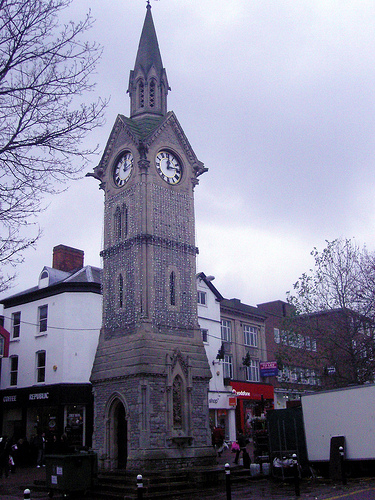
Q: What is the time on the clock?
A: 3.00pm.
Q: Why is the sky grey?
A: It is winter.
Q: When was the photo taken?
A: Day time.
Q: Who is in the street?
A: No one.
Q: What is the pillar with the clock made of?
A: Stone.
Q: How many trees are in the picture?
A: 2.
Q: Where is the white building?
A: Behind the pillar with the clock.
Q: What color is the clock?
A: White.